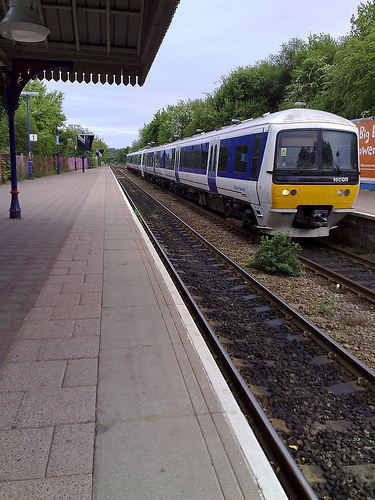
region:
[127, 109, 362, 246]
white, blue and yellow train on tracks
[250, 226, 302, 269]
small bush in between train tracks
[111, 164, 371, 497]
train tracks on the ground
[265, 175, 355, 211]
yellow panel on the front of the train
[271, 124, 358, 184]
front window of the train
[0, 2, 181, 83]
awning over the train stop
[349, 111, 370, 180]
orange sign next to the train tracks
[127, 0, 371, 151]
large green trees growing next to the train tracks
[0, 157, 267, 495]
brick sidewalk next to the train tracks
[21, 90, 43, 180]
blue lamp post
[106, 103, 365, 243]
a municipal transport train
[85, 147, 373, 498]
the rails for a train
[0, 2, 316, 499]
a train station platform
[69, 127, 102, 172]
a train lamp post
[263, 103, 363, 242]
the front cockpit of the train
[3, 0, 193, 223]
a train station balcony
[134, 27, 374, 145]
forests on the the side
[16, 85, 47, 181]
the station number on the lamp post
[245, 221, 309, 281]
a bush on the side of the rails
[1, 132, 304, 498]
a pedestrian sidewalk on a train station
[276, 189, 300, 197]
There are two lights on the left side of the train.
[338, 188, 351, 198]
There are two lights on the right side of the train.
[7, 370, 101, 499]
The pavement is gray.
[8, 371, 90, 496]
The pavement is made of stone.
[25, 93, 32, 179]
The light pole is blue.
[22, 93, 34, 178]
The light pole is made of metal.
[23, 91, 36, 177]
The light pole is slender.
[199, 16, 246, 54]
The sky is blue.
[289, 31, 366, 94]
The trees in the background are green.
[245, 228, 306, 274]
The bush in front of the train is green.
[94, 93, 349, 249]
the train is long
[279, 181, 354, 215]
the bumper is yellow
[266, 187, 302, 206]
The light is on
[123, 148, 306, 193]
the train has 3 cars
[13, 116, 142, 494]
Nobody is waiting for the train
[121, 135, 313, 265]
the train sits on tracks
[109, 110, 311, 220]
the train is mostly white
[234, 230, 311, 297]
A little bush on the tracks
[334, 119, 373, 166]
the sign is orange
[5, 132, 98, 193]
the poles are all blue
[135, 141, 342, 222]
white, blue, and yellow train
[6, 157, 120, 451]
brick loading platform at station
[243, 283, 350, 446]
iron railroad tracks below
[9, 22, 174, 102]
overhang over platform at station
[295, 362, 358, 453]
concrete railroad ties between tracks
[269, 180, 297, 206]
round headlight on train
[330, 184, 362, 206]
round headlight on train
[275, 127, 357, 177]
glass windshield of train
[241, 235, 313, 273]
small bush growing between tracks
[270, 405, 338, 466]
dark gravel on tracks